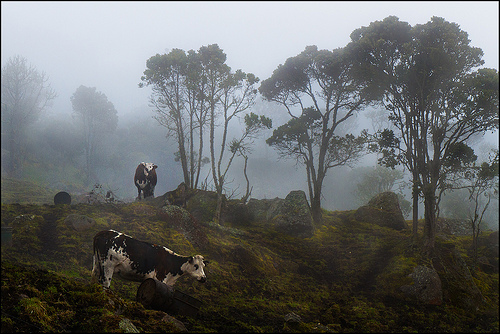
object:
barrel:
[136, 276, 201, 318]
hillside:
[0, 181, 497, 333]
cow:
[92, 228, 208, 294]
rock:
[271, 189, 313, 234]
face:
[191, 259, 208, 283]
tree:
[263, 46, 387, 223]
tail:
[91, 243, 97, 275]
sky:
[1, 2, 497, 137]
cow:
[134, 162, 157, 199]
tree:
[140, 52, 209, 193]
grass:
[0, 176, 500, 334]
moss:
[15, 274, 103, 325]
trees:
[0, 52, 51, 168]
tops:
[140, 43, 249, 87]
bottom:
[94, 230, 112, 252]